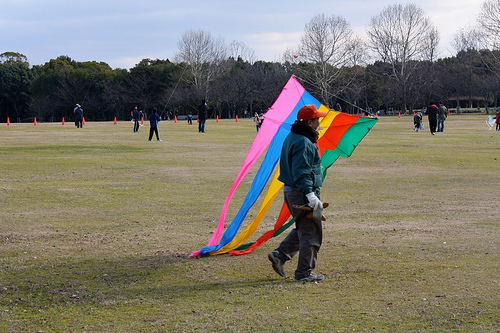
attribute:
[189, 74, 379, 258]
kite — multicolor, large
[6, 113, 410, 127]
cones — orange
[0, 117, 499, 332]
field — green, grassy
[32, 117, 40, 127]
cone — orange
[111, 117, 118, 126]
cone — orange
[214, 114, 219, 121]
cone — orange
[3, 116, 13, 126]
cone — orange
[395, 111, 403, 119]
cone — orange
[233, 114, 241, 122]
cone — orange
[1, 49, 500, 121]
trees — green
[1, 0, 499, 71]
sky — blue